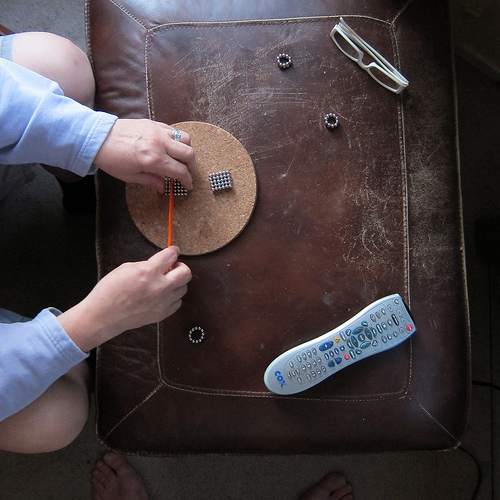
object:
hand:
[97, 115, 197, 196]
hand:
[60, 246, 191, 356]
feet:
[12, 200, 103, 311]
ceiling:
[122, 116, 259, 260]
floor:
[2, 2, 498, 494]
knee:
[33, 28, 94, 97]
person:
[0, 30, 102, 466]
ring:
[174, 324, 209, 346]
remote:
[264, 288, 416, 396]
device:
[166, 173, 173, 279]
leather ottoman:
[241, 83, 424, 329]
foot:
[78, 447, 150, 499]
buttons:
[300, 335, 380, 369]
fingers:
[145, 247, 190, 324]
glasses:
[325, 12, 415, 100]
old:
[363, 188, 438, 263]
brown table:
[82, 1, 474, 452]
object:
[207, 167, 234, 192]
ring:
[170, 127, 180, 140]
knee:
[23, 380, 91, 456]